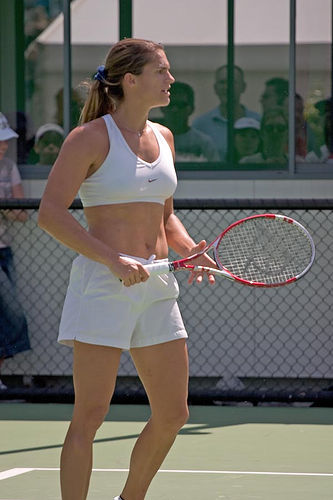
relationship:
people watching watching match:
[28, 122, 65, 166] [33, 35, 192, 498]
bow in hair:
[94, 65, 104, 78] [76, 37, 162, 125]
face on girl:
[132, 53, 179, 108] [52, 24, 210, 492]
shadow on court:
[0, 403, 332, 461] [0, 398, 333, 500]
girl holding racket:
[38, 37, 218, 498] [118, 213, 315, 288]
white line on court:
[186, 463, 320, 482] [98, 418, 326, 496]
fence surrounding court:
[0, 195, 332, 408] [0, 398, 329, 499]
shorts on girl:
[59, 253, 212, 360] [38, 37, 218, 498]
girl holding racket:
[38, 37, 218, 498] [208, 219, 319, 291]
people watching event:
[241, 106, 287, 165] [5, 35, 322, 498]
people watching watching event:
[233, 63, 290, 164] [5, 35, 322, 498]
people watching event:
[0, 107, 31, 389] [5, 35, 322, 498]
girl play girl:
[38, 37, 219, 498] [38, 37, 218, 498]